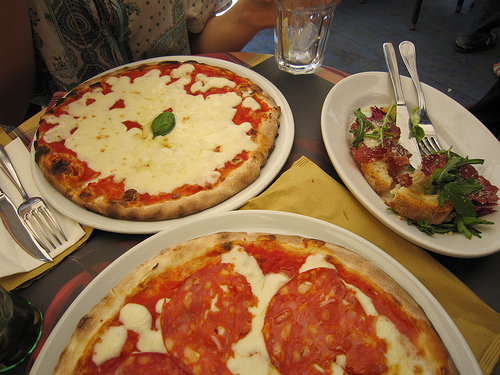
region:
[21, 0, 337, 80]
The person is holding a glass.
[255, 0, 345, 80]
Ice cubes are in the glass.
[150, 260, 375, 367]
Slices of salami are on the pizza.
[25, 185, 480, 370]
A pizza is on a white plate.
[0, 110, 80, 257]
A fork and knife.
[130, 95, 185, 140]
A leaf of basil.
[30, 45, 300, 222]
A cheese pizza.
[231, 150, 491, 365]
A yellow napkin is on the table.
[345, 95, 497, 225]
Bread with salami.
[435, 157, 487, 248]
Leaves of arugula.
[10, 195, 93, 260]
fork next to pizza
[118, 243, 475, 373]
pepperoni on the pizza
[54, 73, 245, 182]
pizza is cheese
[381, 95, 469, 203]
fork and knife on plate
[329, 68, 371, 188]
plate is white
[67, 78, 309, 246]
pizza has not been eaten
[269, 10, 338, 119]
glass has ice cubes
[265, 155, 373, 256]
napkin is yellow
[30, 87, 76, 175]
burned on the edge of pizza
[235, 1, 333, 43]
person is holding the glass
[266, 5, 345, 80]
Empty glass on edge of table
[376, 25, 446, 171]
Fork and knife on plate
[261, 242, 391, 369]
Large piece of pepperoni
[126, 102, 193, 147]
Basil leaf on pizza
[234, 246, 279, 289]
White cheese on pizza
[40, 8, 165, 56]
Patterned shirt on lady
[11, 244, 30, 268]
White napkin under silverware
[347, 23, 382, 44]
Gray wooden floor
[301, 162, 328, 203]
beige place mat under plate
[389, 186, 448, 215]
Crust of pizza on plate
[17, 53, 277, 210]
a cheese pizza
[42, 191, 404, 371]
a pizza with fresh tomatos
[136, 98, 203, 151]
a leaf of basil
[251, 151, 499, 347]
a yellow napkin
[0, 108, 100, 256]
a silver knive and fork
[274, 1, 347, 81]
a glass with ice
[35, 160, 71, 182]
burned bubbles on pizza crust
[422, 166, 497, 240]
green arugala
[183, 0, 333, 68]
a woman's hand holding a glass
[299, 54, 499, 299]
a white oval plate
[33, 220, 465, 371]
A pepperoni pizza is on the table.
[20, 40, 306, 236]
A cheese pizza is on the table.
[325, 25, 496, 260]
A knife and fork next to food on a plate.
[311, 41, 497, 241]
The plate is white.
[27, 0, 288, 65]
A person sitting at the table.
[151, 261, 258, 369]
A pepperoni on the pizza.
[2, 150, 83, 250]
A fork on the napkin.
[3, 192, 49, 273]
A knife is next to the fork.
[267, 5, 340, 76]
The glass is clear.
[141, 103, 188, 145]
A basil leaf on the cheese pizza.